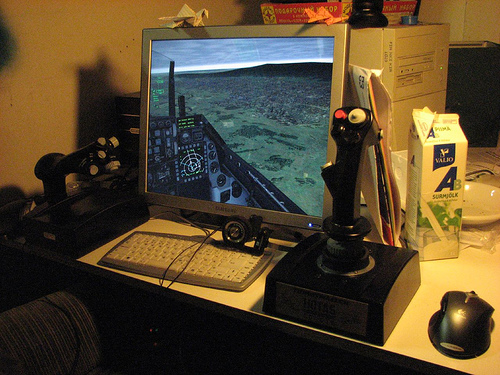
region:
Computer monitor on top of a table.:
[141, 24, 355, 226]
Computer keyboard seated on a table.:
[94, 224, 273, 283]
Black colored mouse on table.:
[429, 286, 497, 361]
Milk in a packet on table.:
[411, 107, 469, 259]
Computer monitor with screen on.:
[142, 22, 352, 226]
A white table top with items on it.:
[80, 149, 474, 374]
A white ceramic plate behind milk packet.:
[394, 177, 498, 231]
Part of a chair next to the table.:
[4, 267, 104, 374]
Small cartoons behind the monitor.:
[259, 0, 426, 27]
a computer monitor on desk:
[138, 21, 340, 244]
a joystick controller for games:
[263, 89, 411, 351]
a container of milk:
[402, 103, 486, 279]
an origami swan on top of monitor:
[155, 5, 217, 35]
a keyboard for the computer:
[111, 225, 280, 307]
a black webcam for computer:
[221, 219, 281, 254]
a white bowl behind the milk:
[432, 167, 497, 239]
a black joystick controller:
[263, 98, 439, 343]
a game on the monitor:
[156, 38, 323, 201]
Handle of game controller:
[315, 107, 383, 284]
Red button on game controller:
[332, 107, 346, 123]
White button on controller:
[348, 106, 366, 126]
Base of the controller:
[255, 229, 425, 349]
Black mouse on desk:
[424, 282, 496, 363]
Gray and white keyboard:
[95, 229, 277, 294]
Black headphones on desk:
[177, 206, 277, 260]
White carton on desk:
[402, 102, 474, 265]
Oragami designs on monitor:
[152, 2, 352, 34]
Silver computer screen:
[135, 21, 355, 243]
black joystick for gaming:
[318, 107, 380, 272]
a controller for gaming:
[291, 100, 398, 285]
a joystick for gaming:
[320, 97, 387, 267]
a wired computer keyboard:
[111, 226, 263, 292]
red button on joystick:
[333, 108, 350, 121]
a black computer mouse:
[427, 276, 489, 358]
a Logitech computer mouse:
[426, 285, 486, 355]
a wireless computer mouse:
[432, 280, 496, 363]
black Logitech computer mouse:
[433, 269, 492, 365]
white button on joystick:
[348, 100, 370, 126]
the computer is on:
[132, 23, 357, 251]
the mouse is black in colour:
[428, 267, 496, 366]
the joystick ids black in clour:
[318, 95, 391, 325]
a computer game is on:
[153, 29, 329, 221]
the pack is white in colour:
[401, 95, 464, 252]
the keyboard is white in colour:
[92, 214, 272, 295]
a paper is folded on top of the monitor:
[143, 4, 216, 31]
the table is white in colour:
[433, 255, 484, 299]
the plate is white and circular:
[459, 176, 499, 222]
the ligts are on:
[117, 318, 168, 365]